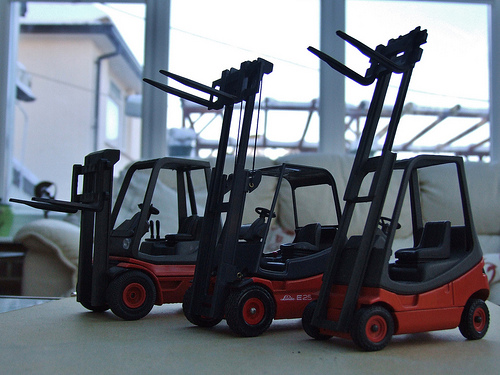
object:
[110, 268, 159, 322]
front wheel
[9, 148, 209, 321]
lift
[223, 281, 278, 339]
front wheel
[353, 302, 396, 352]
front wheel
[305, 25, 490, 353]
lift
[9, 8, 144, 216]
building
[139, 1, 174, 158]
support pillar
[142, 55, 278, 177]
lever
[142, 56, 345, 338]
lift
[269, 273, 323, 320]
bottom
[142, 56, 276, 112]
arm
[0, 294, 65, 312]
drain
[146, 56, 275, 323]
fork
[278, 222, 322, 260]
chair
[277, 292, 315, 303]
decal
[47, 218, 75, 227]
slab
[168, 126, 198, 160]
tower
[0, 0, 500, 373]
photo